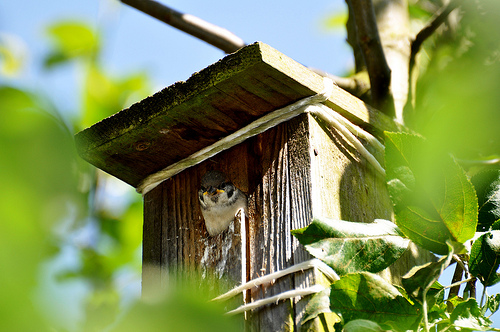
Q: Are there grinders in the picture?
A: No, there are no grinders.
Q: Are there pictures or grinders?
A: No, there are no grinders or pictures.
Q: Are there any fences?
A: No, there are no fences.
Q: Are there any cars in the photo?
A: No, there are no cars.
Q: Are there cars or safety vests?
A: No, there are no cars or safety vests.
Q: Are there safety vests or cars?
A: No, there are no cars or safety vests.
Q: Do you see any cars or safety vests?
A: No, there are no cars or safety vests.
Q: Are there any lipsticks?
A: No, there are no lipsticks.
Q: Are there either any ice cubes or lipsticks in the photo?
A: No, there are no lipsticks or ice cubes.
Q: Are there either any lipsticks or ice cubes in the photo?
A: No, there are no lipsticks or ice cubes.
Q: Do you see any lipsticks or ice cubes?
A: No, there are no lipsticks or ice cubes.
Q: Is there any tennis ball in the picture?
A: No, there are no tennis balls.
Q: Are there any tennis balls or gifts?
A: No, there are no tennis balls or gifts.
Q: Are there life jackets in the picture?
A: No, there are no life jackets.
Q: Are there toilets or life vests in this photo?
A: No, there are no life vests or toilets.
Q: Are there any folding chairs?
A: No, there are no folding chairs.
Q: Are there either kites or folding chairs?
A: No, there are no folding chairs or kites.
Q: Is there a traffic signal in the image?
A: No, there are no traffic lights.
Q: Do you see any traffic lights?
A: No, there are no traffic lights.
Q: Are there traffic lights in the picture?
A: No, there are no traffic lights.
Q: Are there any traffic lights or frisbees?
A: No, there are no traffic lights or frisbees.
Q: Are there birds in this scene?
A: Yes, there is a bird.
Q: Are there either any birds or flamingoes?
A: Yes, there is a bird.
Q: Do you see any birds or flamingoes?
A: Yes, there is a bird.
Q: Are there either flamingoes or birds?
A: Yes, there is a bird.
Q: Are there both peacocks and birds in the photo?
A: No, there is a bird but no peacocks.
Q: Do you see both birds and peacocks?
A: No, there is a bird but no peacocks.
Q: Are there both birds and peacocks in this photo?
A: No, there is a bird but no peacocks.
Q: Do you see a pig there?
A: No, there are no pigs.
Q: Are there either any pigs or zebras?
A: No, there are no pigs or zebras.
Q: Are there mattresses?
A: No, there are no mattresses.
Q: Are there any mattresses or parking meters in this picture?
A: No, there are no mattresses or parking meters.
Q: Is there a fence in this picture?
A: No, there are no fences.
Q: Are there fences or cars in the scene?
A: No, there are no fences or cars.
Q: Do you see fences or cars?
A: No, there are no fences or cars.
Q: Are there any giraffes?
A: No, there are no giraffes.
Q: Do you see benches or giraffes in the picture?
A: No, there are no giraffes or benches.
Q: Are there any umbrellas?
A: No, there are no umbrellas.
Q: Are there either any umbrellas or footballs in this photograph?
A: No, there are no umbrellas or footballs.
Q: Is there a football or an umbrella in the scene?
A: No, there are no umbrellas or footballs.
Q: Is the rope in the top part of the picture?
A: No, the rope is in the bottom of the image.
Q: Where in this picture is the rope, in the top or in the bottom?
A: The rope is in the bottom of the image.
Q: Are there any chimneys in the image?
A: No, there are no chimneys.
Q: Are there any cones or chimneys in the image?
A: No, there are no chimneys or cones.